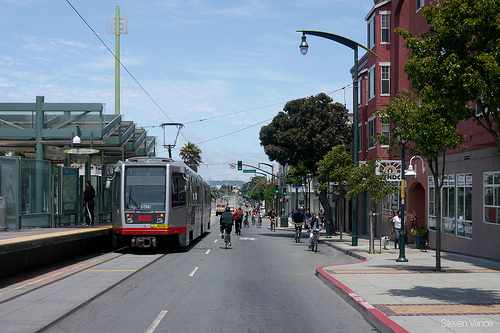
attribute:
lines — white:
[179, 261, 197, 291]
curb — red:
[326, 277, 348, 298]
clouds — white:
[196, 80, 220, 120]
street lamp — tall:
[288, 21, 379, 251]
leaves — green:
[390, 28, 430, 141]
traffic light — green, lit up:
[235, 157, 251, 173]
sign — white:
[371, 160, 403, 182]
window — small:
[376, 10, 395, 50]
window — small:
[362, 17, 378, 52]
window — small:
[379, 59, 392, 96]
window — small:
[365, 64, 375, 105]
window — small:
[352, 77, 363, 112]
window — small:
[377, 110, 392, 151]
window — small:
[365, 119, 378, 150]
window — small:
[475, 165, 498, 246]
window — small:
[424, 173, 439, 234]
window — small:
[451, 174, 478, 243]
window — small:
[440, 170, 455, 240]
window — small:
[415, 171, 455, 240]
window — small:
[362, 117, 381, 155]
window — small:
[374, 10, 394, 45]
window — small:
[363, 15, 375, 56]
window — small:
[362, 9, 378, 49]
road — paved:
[1, 206, 384, 330]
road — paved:
[1, 218, 373, 331]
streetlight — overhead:
[292, 28, 362, 72]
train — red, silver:
[104, 154, 216, 251]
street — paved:
[2, 209, 377, 331]